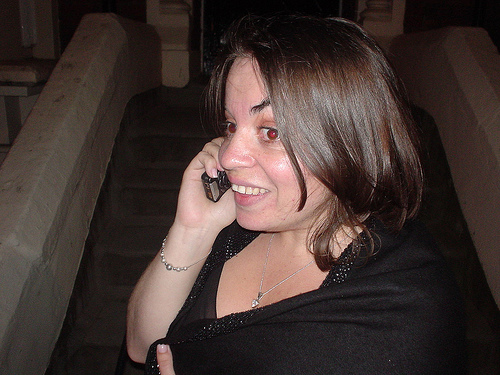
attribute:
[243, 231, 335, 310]
necklace — silver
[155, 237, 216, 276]
bracelet — silver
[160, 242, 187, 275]
charms — silver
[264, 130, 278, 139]
eye — red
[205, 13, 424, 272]
hair — dark brown, shiny, curled, long, brown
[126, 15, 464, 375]
woman — talking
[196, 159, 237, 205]
cell phone — black, small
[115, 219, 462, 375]
sweater — black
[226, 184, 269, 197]
teeth — yellow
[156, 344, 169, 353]
fingernail — shiny